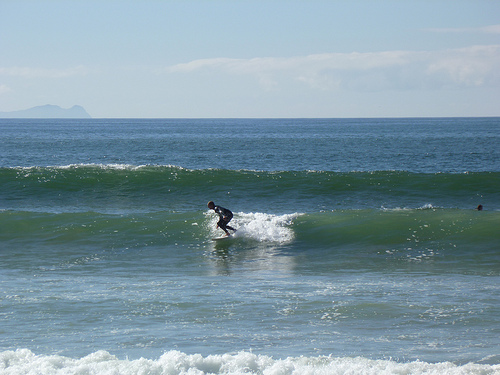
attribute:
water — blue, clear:
[89, 256, 328, 340]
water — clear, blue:
[38, 218, 146, 335]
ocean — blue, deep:
[9, 120, 486, 165]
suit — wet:
[214, 208, 234, 229]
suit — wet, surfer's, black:
[213, 205, 240, 232]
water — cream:
[48, 311, 382, 342]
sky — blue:
[54, 0, 425, 115]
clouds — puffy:
[194, 50, 398, 74]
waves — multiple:
[29, 145, 131, 245]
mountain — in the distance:
[5, 97, 94, 117]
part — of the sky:
[178, 20, 228, 89]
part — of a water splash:
[257, 222, 282, 243]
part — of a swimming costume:
[216, 209, 225, 217]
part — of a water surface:
[356, 296, 401, 327]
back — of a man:
[218, 204, 228, 213]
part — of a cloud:
[325, 55, 364, 73]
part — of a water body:
[251, 127, 391, 176]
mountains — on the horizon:
[5, 100, 97, 121]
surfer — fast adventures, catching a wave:
[205, 198, 241, 239]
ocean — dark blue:
[14, 120, 457, 169]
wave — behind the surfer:
[5, 159, 432, 238]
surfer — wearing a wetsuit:
[206, 198, 239, 236]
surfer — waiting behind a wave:
[472, 198, 483, 210]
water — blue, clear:
[353, 239, 405, 297]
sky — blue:
[2, 5, 484, 120]